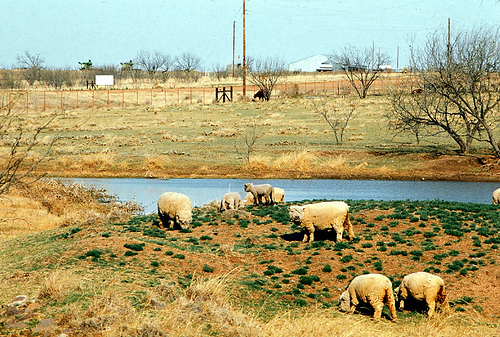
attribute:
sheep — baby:
[244, 176, 273, 199]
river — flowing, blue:
[301, 181, 348, 196]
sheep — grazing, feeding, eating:
[160, 192, 192, 233]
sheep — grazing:
[337, 272, 393, 313]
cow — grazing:
[253, 82, 278, 103]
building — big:
[289, 58, 316, 73]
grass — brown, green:
[169, 232, 205, 240]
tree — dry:
[312, 100, 356, 145]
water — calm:
[308, 181, 329, 193]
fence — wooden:
[216, 85, 235, 109]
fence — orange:
[43, 94, 68, 108]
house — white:
[94, 73, 115, 87]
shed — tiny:
[101, 75, 116, 90]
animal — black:
[243, 86, 269, 101]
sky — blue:
[177, 17, 214, 33]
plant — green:
[433, 205, 459, 222]